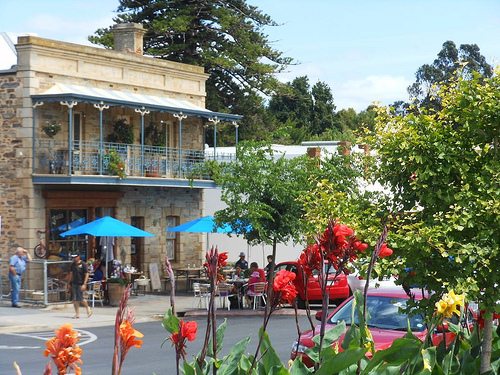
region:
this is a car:
[371, 289, 411, 341]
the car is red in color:
[373, 327, 388, 348]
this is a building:
[4, 52, 179, 192]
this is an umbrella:
[88, 215, 121, 233]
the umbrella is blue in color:
[97, 217, 116, 234]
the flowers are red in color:
[301, 228, 358, 266]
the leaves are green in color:
[407, 115, 489, 185]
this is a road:
[231, 311, 253, 332]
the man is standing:
[6, 242, 33, 294]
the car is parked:
[372, 330, 383, 342]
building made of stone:
[2, 32, 203, 297]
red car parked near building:
[273, 258, 349, 308]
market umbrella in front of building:
[55, 211, 150, 272]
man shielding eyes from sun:
[6, 245, 26, 307]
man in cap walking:
[65, 250, 95, 315]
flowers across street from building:
[42, 220, 485, 371]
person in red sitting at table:
[242, 261, 263, 307]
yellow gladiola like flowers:
[430, 287, 470, 369]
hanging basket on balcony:
[40, 103, 62, 134]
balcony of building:
[32, 88, 244, 190]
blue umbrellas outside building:
[65, 216, 273, 268]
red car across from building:
[285, 293, 467, 362]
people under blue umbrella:
[202, 237, 284, 296]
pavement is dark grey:
[77, 318, 235, 362]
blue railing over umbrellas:
[25, 127, 238, 195]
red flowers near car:
[275, 195, 389, 337]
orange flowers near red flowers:
[35, 299, 202, 360]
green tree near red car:
[351, 67, 499, 304]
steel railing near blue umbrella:
[19, 243, 64, 302]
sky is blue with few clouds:
[297, 8, 422, 83]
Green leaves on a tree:
[387, 84, 497, 348]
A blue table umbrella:
[53, 211, 155, 303]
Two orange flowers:
[23, 299, 151, 371]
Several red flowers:
[261, 218, 401, 371]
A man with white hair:
[4, 241, 34, 312]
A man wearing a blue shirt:
[8, 242, 31, 281]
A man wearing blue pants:
[5, 245, 32, 310]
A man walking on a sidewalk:
[51, 242, 119, 329]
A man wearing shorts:
[65, 248, 100, 325]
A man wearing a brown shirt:
[61, 247, 92, 297]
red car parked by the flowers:
[291, 285, 498, 370]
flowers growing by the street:
[15, 218, 495, 374]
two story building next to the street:
[0, 23, 217, 298]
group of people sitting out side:
[205, 249, 281, 313]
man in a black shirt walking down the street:
[59, 248, 94, 324]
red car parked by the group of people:
[257, 253, 352, 311]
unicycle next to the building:
[27, 226, 61, 264]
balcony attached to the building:
[27, 83, 251, 199]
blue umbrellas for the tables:
[57, 196, 290, 258]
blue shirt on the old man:
[5, 251, 30, 279]